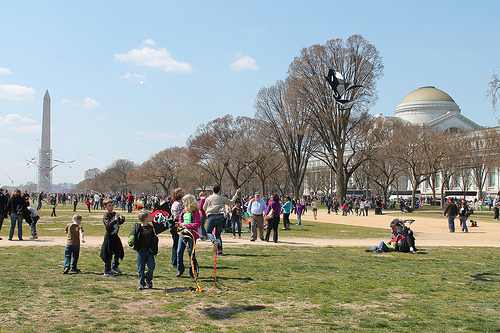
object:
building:
[285, 85, 500, 204]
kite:
[150, 209, 176, 231]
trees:
[188, 114, 285, 215]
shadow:
[201, 303, 267, 321]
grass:
[0, 243, 499, 332]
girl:
[175, 194, 201, 277]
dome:
[391, 85, 463, 114]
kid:
[97, 200, 124, 275]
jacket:
[98, 233, 124, 262]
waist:
[104, 231, 120, 236]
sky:
[0, 1, 499, 188]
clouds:
[112, 38, 195, 74]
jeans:
[103, 252, 123, 274]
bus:
[440, 189, 483, 204]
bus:
[387, 188, 421, 204]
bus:
[345, 189, 370, 199]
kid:
[127, 209, 164, 290]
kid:
[62, 213, 87, 274]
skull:
[153, 212, 165, 222]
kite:
[25, 156, 46, 171]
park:
[0, 188, 498, 329]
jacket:
[174, 208, 204, 239]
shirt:
[64, 222, 85, 245]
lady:
[263, 193, 281, 243]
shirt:
[266, 201, 283, 219]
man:
[246, 191, 267, 242]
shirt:
[246, 199, 268, 215]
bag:
[251, 197, 255, 204]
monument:
[35, 88, 54, 196]